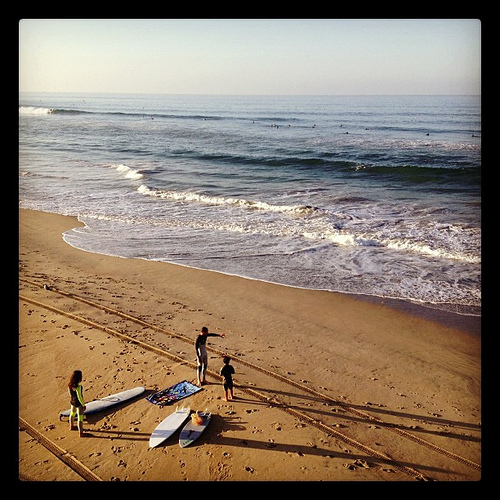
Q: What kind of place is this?
A: It is a shore.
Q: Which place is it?
A: It is a shore.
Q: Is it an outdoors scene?
A: Yes, it is outdoors.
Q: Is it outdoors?
A: Yes, it is outdoors.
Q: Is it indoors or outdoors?
A: It is outdoors.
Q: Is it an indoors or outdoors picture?
A: It is outdoors.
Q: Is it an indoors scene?
A: No, it is outdoors.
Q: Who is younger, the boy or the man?
A: The boy is younger than the man.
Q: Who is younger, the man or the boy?
A: The boy is younger than the man.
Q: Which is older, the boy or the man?
A: The man is older than the boy.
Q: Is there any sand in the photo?
A: Yes, there is sand.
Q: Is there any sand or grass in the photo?
A: Yes, there is sand.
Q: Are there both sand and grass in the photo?
A: No, there is sand but no grass.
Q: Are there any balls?
A: No, there are no balls.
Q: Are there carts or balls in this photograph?
A: No, there are no balls or carts.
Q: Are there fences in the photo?
A: No, there are no fences.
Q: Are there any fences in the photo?
A: No, there are no fences.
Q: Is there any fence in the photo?
A: No, there are no fences.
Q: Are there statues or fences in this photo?
A: No, there are no fences or statues.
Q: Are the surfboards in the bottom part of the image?
A: Yes, the surfboards are in the bottom of the image.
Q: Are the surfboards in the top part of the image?
A: No, the surfboards are in the bottom of the image.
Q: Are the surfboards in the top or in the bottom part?
A: The surfboards are in the bottom of the image.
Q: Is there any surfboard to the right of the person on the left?
A: Yes, there are surfboards to the right of the person.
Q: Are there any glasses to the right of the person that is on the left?
A: No, there are surfboards to the right of the person.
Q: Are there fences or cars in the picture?
A: No, there are no fences or cars.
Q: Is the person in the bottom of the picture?
A: Yes, the person is in the bottom of the image.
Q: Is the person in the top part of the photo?
A: No, the person is in the bottom of the image.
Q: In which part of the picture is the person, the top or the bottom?
A: The person is in the bottom of the image.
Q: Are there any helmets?
A: No, there are no helmets.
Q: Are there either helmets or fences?
A: No, there are no helmets or fences.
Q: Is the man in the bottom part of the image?
A: Yes, the man is in the bottom of the image.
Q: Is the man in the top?
A: No, the man is in the bottom of the image.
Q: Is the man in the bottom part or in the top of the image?
A: The man is in the bottom of the image.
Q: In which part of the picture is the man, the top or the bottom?
A: The man is in the bottom of the image.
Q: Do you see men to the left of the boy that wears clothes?
A: Yes, there is a man to the left of the boy.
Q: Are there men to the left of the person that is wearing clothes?
A: Yes, there is a man to the left of the boy.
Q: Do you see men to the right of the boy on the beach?
A: No, the man is to the left of the boy.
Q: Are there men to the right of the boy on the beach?
A: No, the man is to the left of the boy.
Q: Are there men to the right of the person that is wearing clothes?
A: No, the man is to the left of the boy.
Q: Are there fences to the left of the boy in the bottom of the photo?
A: No, there is a man to the left of the boy.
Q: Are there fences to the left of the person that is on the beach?
A: No, there is a man to the left of the boy.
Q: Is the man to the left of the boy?
A: Yes, the man is to the left of the boy.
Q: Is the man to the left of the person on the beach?
A: Yes, the man is to the left of the boy.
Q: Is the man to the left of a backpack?
A: No, the man is to the left of the boy.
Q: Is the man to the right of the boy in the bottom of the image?
A: No, the man is to the left of the boy.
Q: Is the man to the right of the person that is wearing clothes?
A: No, the man is to the left of the boy.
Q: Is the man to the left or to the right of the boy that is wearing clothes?
A: The man is to the left of the boy.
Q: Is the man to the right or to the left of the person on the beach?
A: The man is to the left of the boy.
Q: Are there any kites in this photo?
A: No, there are no kites.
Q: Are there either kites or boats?
A: No, there are no kites or boats.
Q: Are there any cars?
A: No, there are no cars.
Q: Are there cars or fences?
A: No, there are no cars or fences.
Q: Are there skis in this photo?
A: No, there are no skis.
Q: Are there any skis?
A: No, there are no skis.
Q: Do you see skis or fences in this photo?
A: No, there are no skis or fences.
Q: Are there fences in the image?
A: No, there are no fences.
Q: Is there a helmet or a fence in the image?
A: No, there are no fences or helmets.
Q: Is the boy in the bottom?
A: Yes, the boy is in the bottom of the image.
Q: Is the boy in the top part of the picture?
A: No, the boy is in the bottom of the image.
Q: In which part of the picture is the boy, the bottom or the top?
A: The boy is in the bottom of the image.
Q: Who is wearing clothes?
A: The boy is wearing clothes.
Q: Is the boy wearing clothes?
A: Yes, the boy is wearing clothes.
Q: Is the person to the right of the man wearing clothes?
A: Yes, the boy is wearing clothes.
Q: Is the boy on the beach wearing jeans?
A: No, the boy is wearing clothes.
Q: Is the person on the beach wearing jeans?
A: No, the boy is wearing clothes.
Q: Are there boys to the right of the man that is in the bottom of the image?
A: Yes, there is a boy to the right of the man.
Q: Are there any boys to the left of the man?
A: No, the boy is to the right of the man.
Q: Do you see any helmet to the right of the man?
A: No, there is a boy to the right of the man.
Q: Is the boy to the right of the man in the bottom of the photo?
A: Yes, the boy is to the right of the man.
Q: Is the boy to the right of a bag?
A: No, the boy is to the right of the man.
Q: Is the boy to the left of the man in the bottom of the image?
A: No, the boy is to the right of the man.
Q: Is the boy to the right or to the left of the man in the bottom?
A: The boy is to the right of the man.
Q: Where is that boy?
A: The boy is on the beach.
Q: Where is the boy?
A: The boy is on the beach.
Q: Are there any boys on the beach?
A: Yes, there is a boy on the beach.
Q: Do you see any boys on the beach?
A: Yes, there is a boy on the beach.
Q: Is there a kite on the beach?
A: No, there is a boy on the beach.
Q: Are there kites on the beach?
A: No, there is a boy on the beach.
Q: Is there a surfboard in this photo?
A: Yes, there is a surfboard.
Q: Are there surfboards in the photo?
A: Yes, there is a surfboard.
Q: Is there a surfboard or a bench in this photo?
A: Yes, there is a surfboard.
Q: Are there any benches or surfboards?
A: Yes, there is a surfboard.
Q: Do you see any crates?
A: No, there are no crates.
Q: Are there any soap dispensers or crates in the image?
A: No, there are no crates or soap dispensers.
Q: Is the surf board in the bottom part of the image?
A: Yes, the surf board is in the bottom of the image.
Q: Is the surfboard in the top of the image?
A: No, the surfboard is in the bottom of the image.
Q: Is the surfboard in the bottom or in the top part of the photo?
A: The surfboard is in the bottom of the image.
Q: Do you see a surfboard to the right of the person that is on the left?
A: Yes, there is a surfboard to the right of the person.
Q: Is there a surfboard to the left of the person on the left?
A: No, the surfboard is to the right of the person.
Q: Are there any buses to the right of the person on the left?
A: No, there is a surfboard to the right of the person.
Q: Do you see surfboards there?
A: Yes, there is a surfboard.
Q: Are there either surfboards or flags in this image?
A: Yes, there is a surfboard.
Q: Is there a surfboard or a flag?
A: Yes, there is a surfboard.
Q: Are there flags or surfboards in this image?
A: Yes, there is a surfboard.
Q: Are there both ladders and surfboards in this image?
A: No, there is a surfboard but no ladders.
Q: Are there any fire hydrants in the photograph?
A: No, there are no fire hydrants.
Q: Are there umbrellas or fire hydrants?
A: No, there are no fire hydrants or umbrellas.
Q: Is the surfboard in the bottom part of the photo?
A: Yes, the surfboard is in the bottom of the image.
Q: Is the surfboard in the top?
A: No, the surfboard is in the bottom of the image.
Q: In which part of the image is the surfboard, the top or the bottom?
A: The surfboard is in the bottom of the image.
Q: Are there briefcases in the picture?
A: No, there are no briefcases.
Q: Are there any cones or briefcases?
A: No, there are no briefcases or cones.